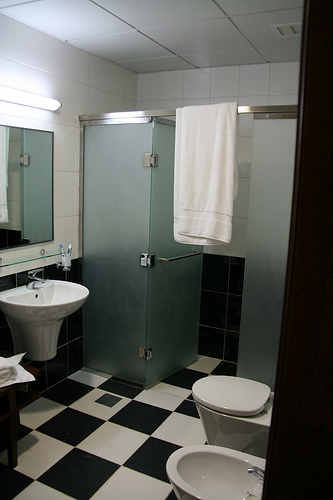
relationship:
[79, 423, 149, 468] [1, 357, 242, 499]
tile on floor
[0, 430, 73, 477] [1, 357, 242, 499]
white tile on floor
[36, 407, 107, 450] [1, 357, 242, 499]
black tile on floor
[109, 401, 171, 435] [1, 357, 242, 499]
black tile on floor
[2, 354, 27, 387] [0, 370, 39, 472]
towels on top of table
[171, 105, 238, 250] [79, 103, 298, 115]
towel over shower bar